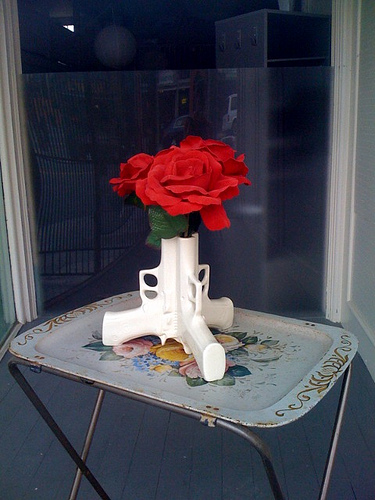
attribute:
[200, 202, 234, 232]
petal — red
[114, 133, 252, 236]
flower — red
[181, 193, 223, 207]
petal — red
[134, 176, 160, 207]
petal — red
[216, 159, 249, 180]
petal — red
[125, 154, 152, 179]
petal — red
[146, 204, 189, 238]
leaf — green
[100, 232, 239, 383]
vase — white, ceramic, unique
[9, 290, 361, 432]
tray — white, gold, rusty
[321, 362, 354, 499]
leg — gray, iron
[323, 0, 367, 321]
frame — white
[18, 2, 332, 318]
window — glass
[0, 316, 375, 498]
floor — wooden